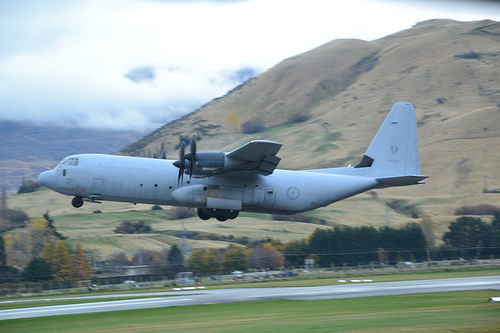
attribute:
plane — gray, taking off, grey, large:
[37, 100, 428, 242]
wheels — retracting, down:
[65, 189, 250, 226]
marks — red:
[177, 284, 198, 293]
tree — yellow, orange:
[39, 235, 97, 293]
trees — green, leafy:
[301, 226, 427, 264]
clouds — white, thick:
[63, 16, 230, 85]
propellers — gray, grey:
[171, 139, 203, 186]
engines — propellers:
[164, 136, 230, 186]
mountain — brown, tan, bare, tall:
[257, 20, 499, 85]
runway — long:
[12, 275, 498, 321]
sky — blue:
[9, 84, 54, 118]